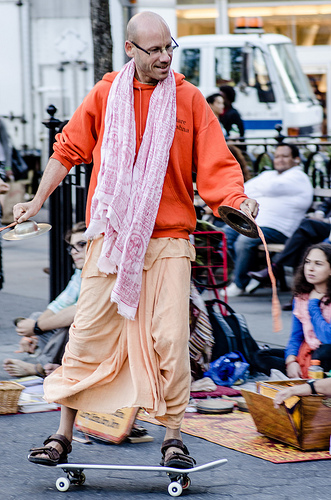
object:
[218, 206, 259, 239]
cymbal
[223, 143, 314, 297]
man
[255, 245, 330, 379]
woman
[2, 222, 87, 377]
man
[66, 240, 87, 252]
glasses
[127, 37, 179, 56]
glasses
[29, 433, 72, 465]
sandals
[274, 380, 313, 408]
hand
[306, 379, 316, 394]
wristwatch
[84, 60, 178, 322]
scarf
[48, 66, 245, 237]
jacket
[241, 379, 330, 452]
box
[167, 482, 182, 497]
wheels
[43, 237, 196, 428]
skirt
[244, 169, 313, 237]
top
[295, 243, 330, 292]
hair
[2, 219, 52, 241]
bell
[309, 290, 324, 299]
hand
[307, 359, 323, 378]
bottle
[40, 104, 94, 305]
railing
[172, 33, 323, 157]
vehicle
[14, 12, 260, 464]
man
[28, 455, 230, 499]
skaterboard